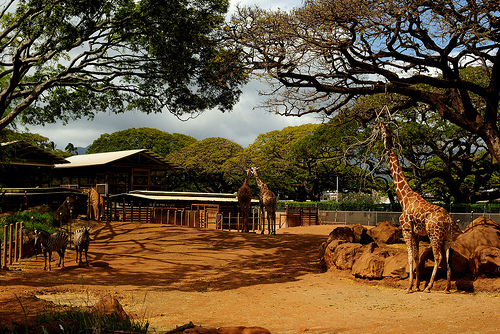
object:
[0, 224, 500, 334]
ground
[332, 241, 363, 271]
rock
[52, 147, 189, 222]
building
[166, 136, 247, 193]
tree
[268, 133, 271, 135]
leaves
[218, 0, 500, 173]
tree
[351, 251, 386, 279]
rock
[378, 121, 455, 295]
giraffe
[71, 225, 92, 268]
zebras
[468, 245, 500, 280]
rocks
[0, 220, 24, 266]
fence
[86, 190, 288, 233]
fence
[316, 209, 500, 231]
fence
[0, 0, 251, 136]
trees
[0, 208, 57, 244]
grass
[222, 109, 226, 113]
leaves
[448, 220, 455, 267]
tail